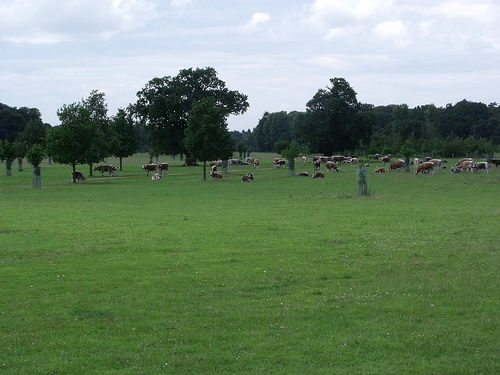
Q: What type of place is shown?
A: It is a field.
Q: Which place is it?
A: It is a field.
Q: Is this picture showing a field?
A: Yes, it is showing a field.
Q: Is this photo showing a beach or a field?
A: It is showing a field.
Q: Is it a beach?
A: No, it is a field.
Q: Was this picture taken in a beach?
A: No, the picture was taken in a field.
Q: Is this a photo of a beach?
A: No, the picture is showing a field.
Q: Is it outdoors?
A: Yes, it is outdoors.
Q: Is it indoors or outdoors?
A: It is outdoors.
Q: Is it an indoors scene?
A: No, it is outdoors.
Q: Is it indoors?
A: No, it is outdoors.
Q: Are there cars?
A: No, there are no cars.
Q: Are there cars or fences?
A: No, there are no cars or fences.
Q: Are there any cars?
A: No, there are no cars.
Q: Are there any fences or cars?
A: No, there are no cars or fences.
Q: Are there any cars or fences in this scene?
A: No, there are no cars or fences.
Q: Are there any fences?
A: No, there are no fences.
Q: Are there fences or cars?
A: No, there are no fences or cars.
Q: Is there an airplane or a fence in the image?
A: No, there are no fences or airplanes.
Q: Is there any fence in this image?
A: No, there are no fences.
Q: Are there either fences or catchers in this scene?
A: No, there are no fences or catchers.